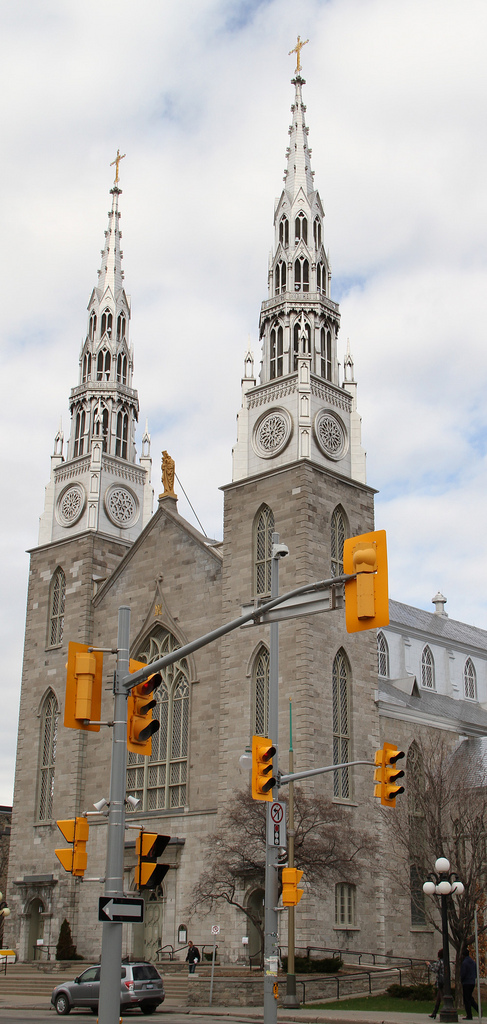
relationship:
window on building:
[113, 619, 190, 811] [78, 526, 243, 926]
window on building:
[35, 561, 71, 659] [25, 499, 146, 761]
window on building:
[21, 688, 64, 829] [21, 548, 114, 867]